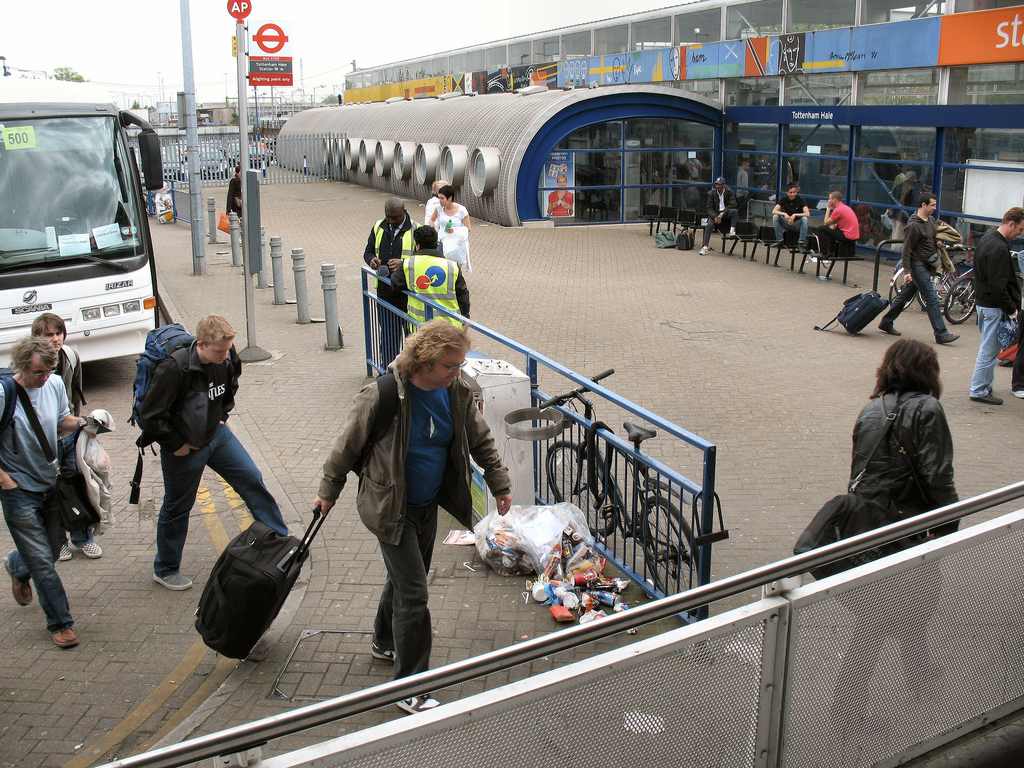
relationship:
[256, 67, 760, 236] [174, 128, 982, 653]
building on side of road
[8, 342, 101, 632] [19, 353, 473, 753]
person walking on street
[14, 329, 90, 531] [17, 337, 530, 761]
person walking on street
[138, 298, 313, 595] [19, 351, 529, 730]
person walking on street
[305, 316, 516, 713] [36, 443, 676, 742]
man walking on sidewalk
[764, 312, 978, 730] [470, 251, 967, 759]
person walking on sidewalk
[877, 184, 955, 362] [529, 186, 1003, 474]
person walking on street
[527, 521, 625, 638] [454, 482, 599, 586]
trash spilling out from trash bag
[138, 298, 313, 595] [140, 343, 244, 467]
person wearing shirt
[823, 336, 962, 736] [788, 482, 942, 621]
person carrying suitcase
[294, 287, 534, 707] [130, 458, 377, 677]
man pulling suitcase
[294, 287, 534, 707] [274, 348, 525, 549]
man in jacket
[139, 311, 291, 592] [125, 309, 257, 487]
person in jacket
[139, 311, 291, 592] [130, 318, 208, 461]
person wearing suitcase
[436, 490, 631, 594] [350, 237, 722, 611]
trash bag by fence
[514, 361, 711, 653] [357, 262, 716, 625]
bike leaning up against fence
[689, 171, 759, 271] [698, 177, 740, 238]
man in jacket